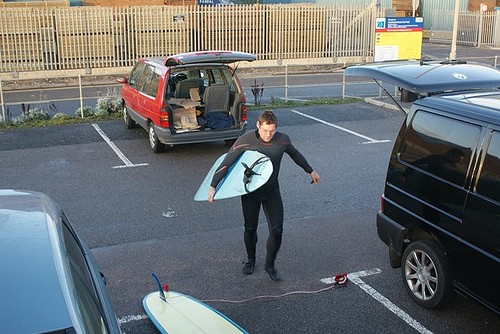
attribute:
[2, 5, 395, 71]
fence — tan, wooden, privacy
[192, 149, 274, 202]
surfboard — blue,  blue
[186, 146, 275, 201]
surfboard — blue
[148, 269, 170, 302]
fin — blue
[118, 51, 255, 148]
van — parked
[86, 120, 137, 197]
asphalt — dark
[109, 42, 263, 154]
vehicle — red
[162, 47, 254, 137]
hatchback — open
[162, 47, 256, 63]
trunk door — open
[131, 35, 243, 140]
car — red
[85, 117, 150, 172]
line — straight, white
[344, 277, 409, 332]
line — straight, white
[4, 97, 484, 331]
lot — parking